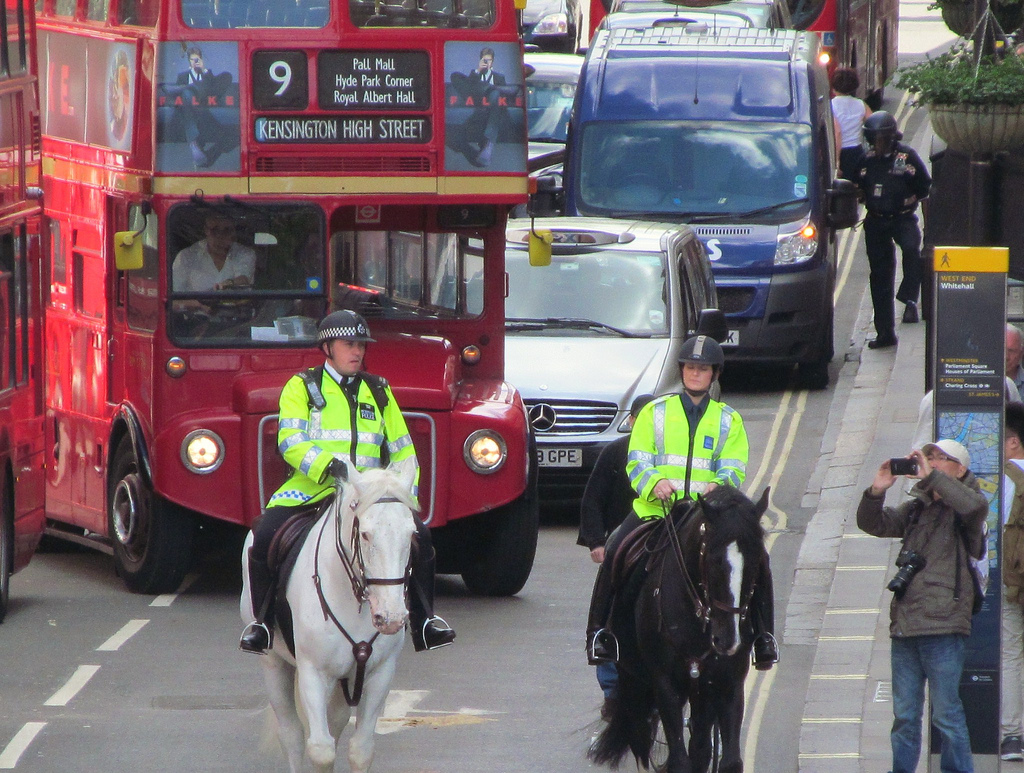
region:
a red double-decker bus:
[43, 15, 556, 601]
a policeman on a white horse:
[267, 312, 429, 765]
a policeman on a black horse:
[597, 326, 788, 769]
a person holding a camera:
[855, 432, 1005, 726]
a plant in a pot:
[894, 19, 1022, 153]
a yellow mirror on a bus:
[96, 217, 161, 269]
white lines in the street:
[1, 599, 163, 768]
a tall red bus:
[30, 2, 536, 590]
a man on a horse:
[253, 307, 434, 747]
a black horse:
[598, 492, 777, 756]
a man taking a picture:
[873, 440, 975, 764]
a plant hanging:
[914, 23, 1017, 148]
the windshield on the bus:
[165, 209, 483, 333]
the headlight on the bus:
[465, 427, 500, 465]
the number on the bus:
[258, 54, 290, 97]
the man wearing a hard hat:
[241, 307, 456, 650]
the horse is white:
[239, 456, 420, 770]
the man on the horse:
[236, 307, 455, 769]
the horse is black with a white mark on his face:
[571, 486, 768, 771]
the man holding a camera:
[852, 437, 985, 770]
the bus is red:
[33, 2, 536, 598]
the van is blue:
[563, 25, 858, 393]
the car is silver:
[501, 215, 726, 516]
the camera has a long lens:
[889, 502, 947, 595]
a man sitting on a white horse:
[241, 306, 453, 769]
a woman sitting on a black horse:
[589, 333, 779, 768]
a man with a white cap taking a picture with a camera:
[854, 438, 988, 768]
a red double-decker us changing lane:
[30, 2, 540, 595]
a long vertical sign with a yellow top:
[934, 245, 1005, 755]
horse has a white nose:
[586, 489, 768, 769]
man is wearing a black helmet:
[241, 309, 453, 655]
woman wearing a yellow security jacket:
[585, 336, 779, 670]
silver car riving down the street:
[433, 214, 716, 519]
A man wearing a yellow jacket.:
[275, 372, 413, 493]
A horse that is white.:
[214, 474, 467, 768]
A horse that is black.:
[549, 483, 794, 759]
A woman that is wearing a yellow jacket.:
[584, 380, 778, 526]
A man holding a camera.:
[879, 448, 930, 478]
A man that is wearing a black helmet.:
[302, 301, 382, 347]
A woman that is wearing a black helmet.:
[666, 328, 727, 382]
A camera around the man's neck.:
[876, 550, 931, 598]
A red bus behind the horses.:
[22, 10, 550, 589]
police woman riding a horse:
[578, 320, 781, 767]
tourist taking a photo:
[848, 420, 991, 752]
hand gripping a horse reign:
[322, 458, 346, 482]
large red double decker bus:
[83, 9, 532, 499]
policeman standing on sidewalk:
[859, 97, 921, 344]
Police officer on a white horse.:
[231, 306, 454, 766]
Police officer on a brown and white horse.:
[582, 328, 780, 766]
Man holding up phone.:
[853, 442, 991, 768]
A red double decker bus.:
[27, 2, 540, 601]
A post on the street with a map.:
[931, 247, 1007, 748]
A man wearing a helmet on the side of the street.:
[852, 114, 930, 358]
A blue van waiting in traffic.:
[568, 23, 853, 385]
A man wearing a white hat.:
[856, 440, 983, 770]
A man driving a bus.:
[166, 203, 265, 346]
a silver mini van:
[479, 191, 730, 499]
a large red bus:
[48, 55, 545, 599]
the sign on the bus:
[256, 52, 438, 139]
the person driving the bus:
[184, 201, 255, 293]